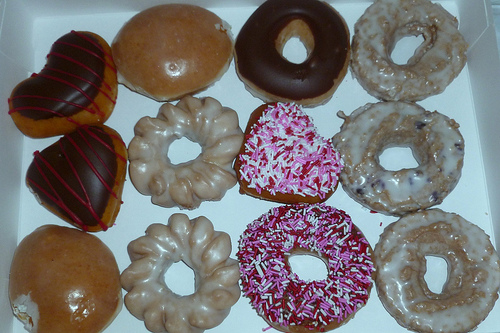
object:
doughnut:
[9, 223, 122, 332]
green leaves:
[233, 97, 341, 205]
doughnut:
[24, 126, 130, 232]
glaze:
[22, 123, 126, 232]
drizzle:
[24, 122, 129, 232]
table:
[215, 194, 255, 226]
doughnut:
[333, 99, 466, 217]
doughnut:
[372, 208, 497, 332]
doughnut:
[120, 213, 241, 332]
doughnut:
[127, 95, 247, 210]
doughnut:
[351, 0, 469, 103]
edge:
[0, 0, 27, 333]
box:
[0, 1, 499, 332]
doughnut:
[239, 99, 465, 217]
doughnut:
[233, 101, 340, 204]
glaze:
[5, 31, 116, 139]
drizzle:
[7, 30, 117, 138]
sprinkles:
[232, 99, 345, 205]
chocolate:
[231, 0, 353, 108]